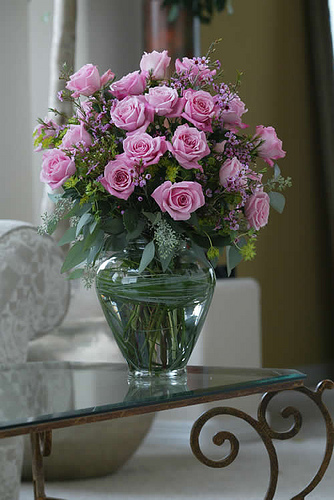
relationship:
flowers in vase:
[32, 50, 287, 232] [93, 238, 216, 377]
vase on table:
[93, 238, 216, 377] [0, 360, 333, 498]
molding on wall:
[138, 6, 240, 277] [160, 104, 213, 148]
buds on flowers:
[183, 115, 209, 128] [32, 50, 287, 232]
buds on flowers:
[31, 38, 293, 292] [32, 50, 287, 232]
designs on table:
[189, 378, 333, 500] [0, 360, 333, 498]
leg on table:
[27, 426, 55, 498] [0, 360, 333, 498]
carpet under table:
[20, 388, 333, 498] [0, 360, 333, 498]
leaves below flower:
[209, 195, 229, 215] [158, 120, 216, 178]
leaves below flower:
[209, 195, 229, 215] [143, 174, 209, 226]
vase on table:
[95, 241, 216, 387] [3, 359, 332, 472]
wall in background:
[229, 0, 332, 217] [1, 2, 323, 291]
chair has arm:
[0, 209, 75, 498] [7, 222, 73, 331]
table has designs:
[0, 359, 307, 433] [189, 378, 333, 500]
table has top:
[2, 340, 329, 438] [1, 354, 311, 443]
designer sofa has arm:
[1, 214, 77, 498] [0, 217, 70, 365]